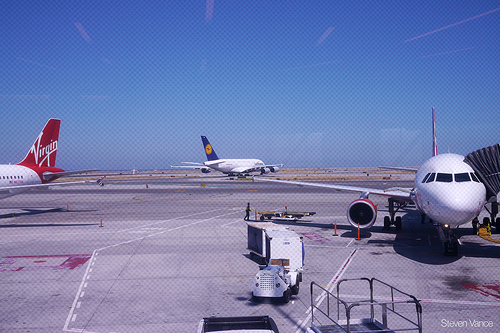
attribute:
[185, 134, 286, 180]
plane — white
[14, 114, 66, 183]
tail — red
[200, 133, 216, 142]
tail — blue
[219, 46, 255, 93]
sky — blue, clear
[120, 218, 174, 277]
pavement — gray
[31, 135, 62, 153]
logo — white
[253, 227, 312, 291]
cart — white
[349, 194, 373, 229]
engine — big